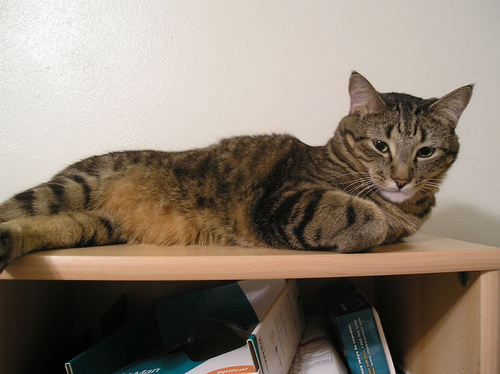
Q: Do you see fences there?
A: No, there are no fences.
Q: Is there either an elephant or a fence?
A: No, there are no fences or elephants.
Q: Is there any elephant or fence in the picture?
A: No, there are no fences or elephants.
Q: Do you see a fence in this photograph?
A: No, there are no fences.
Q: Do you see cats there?
A: Yes, there is a cat.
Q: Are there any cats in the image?
A: Yes, there is a cat.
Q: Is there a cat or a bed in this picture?
A: Yes, there is a cat.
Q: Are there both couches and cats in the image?
A: No, there is a cat but no couches.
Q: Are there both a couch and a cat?
A: No, there is a cat but no couches.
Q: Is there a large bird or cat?
A: Yes, there is a large cat.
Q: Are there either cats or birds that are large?
A: Yes, the cat is large.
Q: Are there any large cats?
A: Yes, there is a large cat.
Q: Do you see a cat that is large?
A: Yes, there is a cat that is large.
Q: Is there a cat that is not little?
A: Yes, there is a large cat.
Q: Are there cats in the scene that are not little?
A: Yes, there is a large cat.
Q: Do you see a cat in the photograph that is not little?
A: Yes, there is a large cat.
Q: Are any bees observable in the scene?
A: No, there are no bees.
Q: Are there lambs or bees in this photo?
A: No, there are no bees or lambs.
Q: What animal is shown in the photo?
A: The animal is a cat.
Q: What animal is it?
A: The animal is a cat.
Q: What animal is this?
A: That is a cat.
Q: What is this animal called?
A: That is a cat.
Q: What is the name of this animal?
A: That is a cat.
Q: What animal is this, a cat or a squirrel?
A: That is a cat.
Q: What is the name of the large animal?
A: The animal is a cat.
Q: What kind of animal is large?
A: The animal is a cat.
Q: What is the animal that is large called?
A: The animal is a cat.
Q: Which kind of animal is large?
A: The animal is a cat.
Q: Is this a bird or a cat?
A: This is a cat.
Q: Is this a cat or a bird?
A: This is a cat.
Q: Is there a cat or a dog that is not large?
A: No, there is a cat but it is large.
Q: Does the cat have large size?
A: Yes, the cat is large.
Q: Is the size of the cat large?
A: Yes, the cat is large.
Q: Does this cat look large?
A: Yes, the cat is large.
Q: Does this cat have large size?
A: Yes, the cat is large.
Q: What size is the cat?
A: The cat is large.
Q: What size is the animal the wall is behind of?
A: The cat is large.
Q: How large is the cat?
A: The cat is large.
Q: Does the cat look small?
A: No, the cat is large.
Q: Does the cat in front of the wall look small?
A: No, the cat is large.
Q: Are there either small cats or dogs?
A: No, there is a cat but it is large.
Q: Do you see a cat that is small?
A: No, there is a cat but it is large.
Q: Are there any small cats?
A: No, there is a cat but it is large.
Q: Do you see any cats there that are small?
A: No, there is a cat but it is large.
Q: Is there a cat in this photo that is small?
A: No, there is a cat but it is large.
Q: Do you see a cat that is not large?
A: No, there is a cat but it is large.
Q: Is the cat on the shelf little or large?
A: The cat is large.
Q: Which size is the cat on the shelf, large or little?
A: The cat is large.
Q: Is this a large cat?
A: Yes, this is a large cat.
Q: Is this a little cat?
A: No, this is a large cat.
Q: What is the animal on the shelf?
A: The animal is a cat.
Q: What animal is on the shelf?
A: The animal is a cat.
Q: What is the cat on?
A: The cat is on the shelf.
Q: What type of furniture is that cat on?
A: The cat is on the shelf.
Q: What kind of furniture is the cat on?
A: The cat is on the shelf.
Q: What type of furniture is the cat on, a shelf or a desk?
A: The cat is on a shelf.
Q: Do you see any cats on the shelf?
A: Yes, there is a cat on the shelf.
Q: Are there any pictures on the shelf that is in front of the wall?
A: No, there is a cat on the shelf.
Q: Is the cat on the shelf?
A: Yes, the cat is on the shelf.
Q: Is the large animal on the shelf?
A: Yes, the cat is on the shelf.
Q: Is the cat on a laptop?
A: No, the cat is on the shelf.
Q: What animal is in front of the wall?
A: The animal is a cat.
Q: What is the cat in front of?
A: The cat is in front of the wall.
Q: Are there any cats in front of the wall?
A: Yes, there is a cat in front of the wall.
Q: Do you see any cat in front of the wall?
A: Yes, there is a cat in front of the wall.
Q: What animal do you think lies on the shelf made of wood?
A: The cat lies on the shelf.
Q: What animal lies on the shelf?
A: The cat lies on the shelf.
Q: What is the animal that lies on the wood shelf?
A: The animal is a cat.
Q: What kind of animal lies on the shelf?
A: The animal is a cat.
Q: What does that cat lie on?
A: The cat lies on the shelf.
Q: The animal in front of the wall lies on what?
A: The cat lies on the shelf.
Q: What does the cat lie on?
A: The cat lies on the shelf.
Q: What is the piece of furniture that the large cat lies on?
A: The piece of furniture is a shelf.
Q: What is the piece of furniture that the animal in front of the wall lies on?
A: The piece of furniture is a shelf.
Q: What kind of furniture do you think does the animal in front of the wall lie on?
A: The cat lies on the shelf.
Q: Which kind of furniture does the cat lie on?
A: The cat lies on the shelf.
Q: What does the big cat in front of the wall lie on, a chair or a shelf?
A: The cat lies on a shelf.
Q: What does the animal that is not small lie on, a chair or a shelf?
A: The cat lies on a shelf.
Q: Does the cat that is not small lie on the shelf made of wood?
A: Yes, the cat lies on the shelf.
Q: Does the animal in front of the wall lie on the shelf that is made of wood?
A: Yes, the cat lies on the shelf.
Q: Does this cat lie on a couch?
A: No, the cat lies on the shelf.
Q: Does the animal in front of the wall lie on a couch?
A: No, the cat lies on the shelf.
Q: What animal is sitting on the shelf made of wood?
A: The animal is a cat.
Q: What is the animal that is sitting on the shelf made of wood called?
A: The animal is a cat.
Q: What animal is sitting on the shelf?
A: The animal is a cat.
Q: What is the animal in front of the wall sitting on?
A: The cat is sitting on the shelf.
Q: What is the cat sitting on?
A: The cat is sitting on the shelf.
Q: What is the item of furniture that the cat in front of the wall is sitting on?
A: The piece of furniture is a shelf.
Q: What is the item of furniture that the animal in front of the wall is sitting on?
A: The piece of furniture is a shelf.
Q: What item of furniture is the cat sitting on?
A: The cat is sitting on the shelf.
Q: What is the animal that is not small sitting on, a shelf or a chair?
A: The cat is sitting on a shelf.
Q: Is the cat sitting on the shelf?
A: Yes, the cat is sitting on the shelf.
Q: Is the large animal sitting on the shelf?
A: Yes, the cat is sitting on the shelf.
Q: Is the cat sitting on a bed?
A: No, the cat is sitting on the shelf.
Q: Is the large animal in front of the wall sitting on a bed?
A: No, the cat is sitting on the shelf.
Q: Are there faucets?
A: No, there are no faucets.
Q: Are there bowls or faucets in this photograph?
A: No, there are no faucets or bowls.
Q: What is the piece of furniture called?
A: The piece of furniture is a shelf.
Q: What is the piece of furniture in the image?
A: The piece of furniture is a shelf.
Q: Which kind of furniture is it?
A: The piece of furniture is a shelf.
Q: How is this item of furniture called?
A: This is a shelf.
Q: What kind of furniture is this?
A: This is a shelf.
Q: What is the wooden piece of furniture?
A: The piece of furniture is a shelf.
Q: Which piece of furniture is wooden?
A: The piece of furniture is a shelf.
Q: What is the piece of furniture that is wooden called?
A: The piece of furniture is a shelf.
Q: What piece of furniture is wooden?
A: The piece of furniture is a shelf.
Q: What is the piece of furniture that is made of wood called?
A: The piece of furniture is a shelf.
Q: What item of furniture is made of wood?
A: The piece of furniture is a shelf.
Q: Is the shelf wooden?
A: Yes, the shelf is wooden.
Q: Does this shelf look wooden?
A: Yes, the shelf is wooden.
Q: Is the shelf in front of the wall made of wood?
A: Yes, the shelf is made of wood.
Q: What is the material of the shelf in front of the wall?
A: The shelf is made of wood.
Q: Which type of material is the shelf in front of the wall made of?
A: The shelf is made of wood.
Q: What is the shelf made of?
A: The shelf is made of wood.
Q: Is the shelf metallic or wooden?
A: The shelf is wooden.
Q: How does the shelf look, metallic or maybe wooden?
A: The shelf is wooden.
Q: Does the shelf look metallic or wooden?
A: The shelf is wooden.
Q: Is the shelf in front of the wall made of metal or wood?
A: The shelf is made of wood.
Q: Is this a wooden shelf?
A: Yes, this is a wooden shelf.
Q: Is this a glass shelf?
A: No, this is a wooden shelf.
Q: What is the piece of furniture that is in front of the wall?
A: The piece of furniture is a shelf.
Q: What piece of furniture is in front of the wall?
A: The piece of furniture is a shelf.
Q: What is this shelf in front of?
A: The shelf is in front of the wall.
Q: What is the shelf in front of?
A: The shelf is in front of the wall.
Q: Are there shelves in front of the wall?
A: Yes, there is a shelf in front of the wall.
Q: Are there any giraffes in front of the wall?
A: No, there is a shelf in front of the wall.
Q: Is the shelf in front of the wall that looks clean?
A: Yes, the shelf is in front of the wall.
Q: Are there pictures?
A: No, there are no pictures.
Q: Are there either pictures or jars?
A: No, there are no pictures or jars.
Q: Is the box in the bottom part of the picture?
A: Yes, the box is in the bottom of the image.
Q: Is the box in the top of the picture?
A: No, the box is in the bottom of the image.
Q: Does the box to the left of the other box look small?
A: Yes, the box is small.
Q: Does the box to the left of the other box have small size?
A: Yes, the box is small.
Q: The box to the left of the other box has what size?
A: The box is small.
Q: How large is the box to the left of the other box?
A: The box is small.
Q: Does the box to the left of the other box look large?
A: No, the box is small.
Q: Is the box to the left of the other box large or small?
A: The box is small.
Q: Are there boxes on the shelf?
A: Yes, there is a box on the shelf.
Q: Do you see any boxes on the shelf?
A: Yes, there is a box on the shelf.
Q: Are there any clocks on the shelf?
A: No, there is a box on the shelf.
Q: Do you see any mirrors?
A: No, there are no mirrors.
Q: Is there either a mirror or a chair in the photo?
A: No, there are no mirrors or chairs.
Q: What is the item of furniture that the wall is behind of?
A: The piece of furniture is a shelf.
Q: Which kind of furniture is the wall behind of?
A: The wall is behind the shelf.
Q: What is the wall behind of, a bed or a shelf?
A: The wall is behind a shelf.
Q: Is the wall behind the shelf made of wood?
A: Yes, the wall is behind the shelf.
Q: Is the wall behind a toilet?
A: No, the wall is behind the shelf.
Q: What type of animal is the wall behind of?
A: The wall is behind the cat.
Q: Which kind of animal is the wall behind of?
A: The wall is behind the cat.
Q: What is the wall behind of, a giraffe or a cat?
A: The wall is behind a cat.